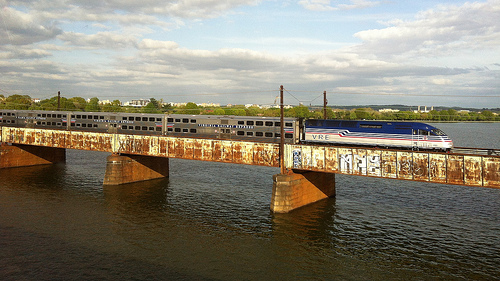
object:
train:
[224, 115, 454, 150]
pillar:
[269, 169, 335, 213]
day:
[128, 7, 265, 90]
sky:
[258, 14, 372, 49]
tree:
[364, 106, 463, 120]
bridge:
[306, 147, 414, 180]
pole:
[279, 84, 284, 175]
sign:
[312, 134, 330, 140]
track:
[458, 147, 495, 155]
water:
[329, 175, 432, 242]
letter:
[312, 134, 330, 140]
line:
[300, 90, 499, 98]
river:
[63, 180, 243, 275]